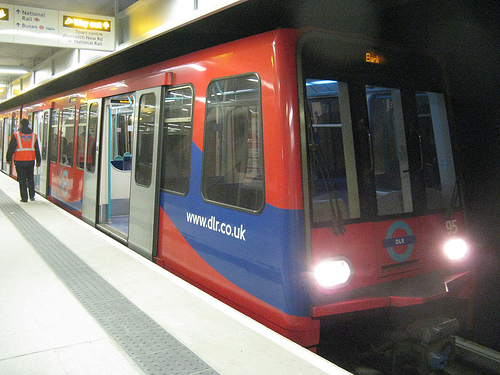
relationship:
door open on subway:
[97, 96, 160, 248] [0, 25, 497, 352]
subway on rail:
[6, 45, 478, 339] [322, 320, 498, 372]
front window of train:
[308, 76, 455, 241] [1, 54, 488, 368]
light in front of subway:
[309, 230, 471, 290] [0, 25, 497, 352]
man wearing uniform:
[3, 115, 46, 202] [7, 125, 47, 196]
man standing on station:
[5, 118, 41, 202] [6, 3, 498, 373]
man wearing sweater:
[5, 118, 41, 202] [1, 122, 43, 169]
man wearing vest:
[3, 115, 46, 202] [9, 126, 39, 163]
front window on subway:
[298, 73, 463, 227] [0, 25, 497, 352]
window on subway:
[202, 65, 266, 215] [0, 25, 497, 352]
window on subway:
[156, 79, 198, 196] [0, 25, 497, 352]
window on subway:
[135, 92, 155, 188] [0, 25, 497, 352]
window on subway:
[72, 95, 92, 171] [0, 25, 497, 352]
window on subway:
[55, 99, 80, 169] [0, 25, 497, 352]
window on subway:
[41, 100, 58, 160] [0, 25, 497, 352]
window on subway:
[205, 70, 265, 209] [0, 25, 497, 352]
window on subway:
[132, 87, 161, 187] [0, 25, 497, 352]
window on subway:
[58, 106, 74, 168] [0, 25, 497, 352]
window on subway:
[197, 70, 262, 210] [0, 25, 497, 352]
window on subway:
[202, 65, 266, 215] [0, 17, 487, 360]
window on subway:
[154, 77, 195, 196] [0, 17, 487, 360]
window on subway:
[82, 98, 101, 174] [0, 17, 487, 360]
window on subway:
[47, 110, 60, 164] [0, 17, 487, 360]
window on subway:
[36, 106, 50, 166] [0, 17, 487, 360]